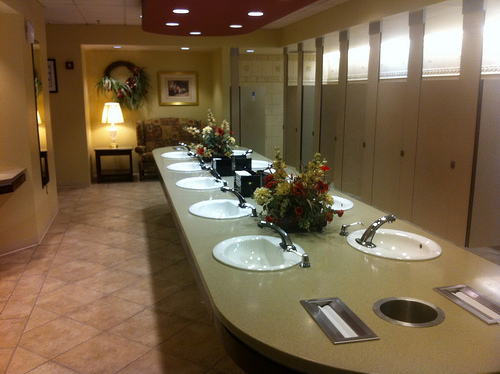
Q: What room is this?
A: Bathroom.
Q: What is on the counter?
A: Flowers.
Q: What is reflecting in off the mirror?
A: Stalls.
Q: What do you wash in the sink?
A: Hands.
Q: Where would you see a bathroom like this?
A: Hotel.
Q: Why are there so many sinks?
A: Accommodate a lot of people.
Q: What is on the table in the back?
A: Lamp.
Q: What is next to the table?
A: Chair.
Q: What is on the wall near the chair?
A: Picture.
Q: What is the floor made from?
A: Tile.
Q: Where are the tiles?
A: On ground.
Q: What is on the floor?
A: Tiles.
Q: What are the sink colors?
A: White.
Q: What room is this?
A: Bathroom.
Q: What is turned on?
A: A lamp.